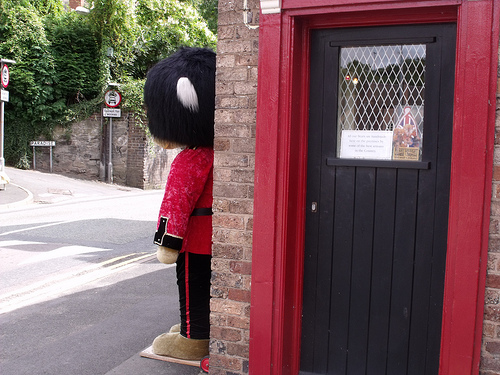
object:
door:
[276, 10, 460, 373]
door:
[249, 0, 499, 375]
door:
[301, 23, 459, 375]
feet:
[154, 321, 208, 360]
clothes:
[153, 148, 211, 338]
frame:
[250, 0, 498, 373]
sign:
[30, 139, 54, 147]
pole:
[32, 145, 36, 166]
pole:
[49, 146, 53, 172]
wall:
[28, 110, 182, 189]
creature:
[141, 45, 215, 360]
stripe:
[184, 252, 189, 337]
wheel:
[200, 354, 210, 371]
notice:
[340, 127, 395, 158]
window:
[336, 44, 426, 159]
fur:
[176, 75, 199, 110]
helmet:
[142, 47, 215, 146]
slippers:
[152, 322, 207, 358]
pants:
[175, 251, 210, 339]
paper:
[336, 128, 398, 162]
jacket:
[154, 143, 217, 260]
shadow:
[0, 216, 190, 270]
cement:
[1, 164, 202, 374]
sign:
[102, 85, 123, 183]